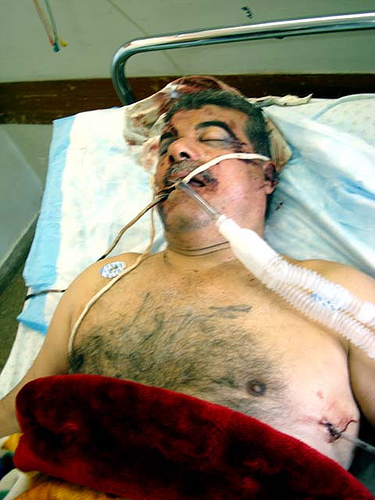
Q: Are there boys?
A: No, there are no boys.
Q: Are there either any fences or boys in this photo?
A: No, there are no boys or fences.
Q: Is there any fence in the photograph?
A: No, there are no fences.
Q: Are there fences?
A: No, there are no fences.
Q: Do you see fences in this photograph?
A: No, there are no fences.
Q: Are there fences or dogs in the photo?
A: No, there are no fences or dogs.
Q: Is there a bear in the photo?
A: No, there are no bears.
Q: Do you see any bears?
A: No, there are no bears.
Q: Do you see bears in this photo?
A: No, there are no bears.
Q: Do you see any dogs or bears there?
A: No, there are no bears or dogs.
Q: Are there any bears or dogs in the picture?
A: No, there are no bears or dogs.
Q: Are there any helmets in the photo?
A: No, there are no helmets.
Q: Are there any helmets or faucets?
A: No, there are no helmets or faucets.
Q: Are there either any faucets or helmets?
A: No, there are no helmets or faucets.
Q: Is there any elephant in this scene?
A: No, there are no elephants.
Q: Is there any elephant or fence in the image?
A: No, there are no elephants or fences.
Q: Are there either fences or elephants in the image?
A: No, there are no elephants or fences.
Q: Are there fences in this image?
A: No, there are no fences.